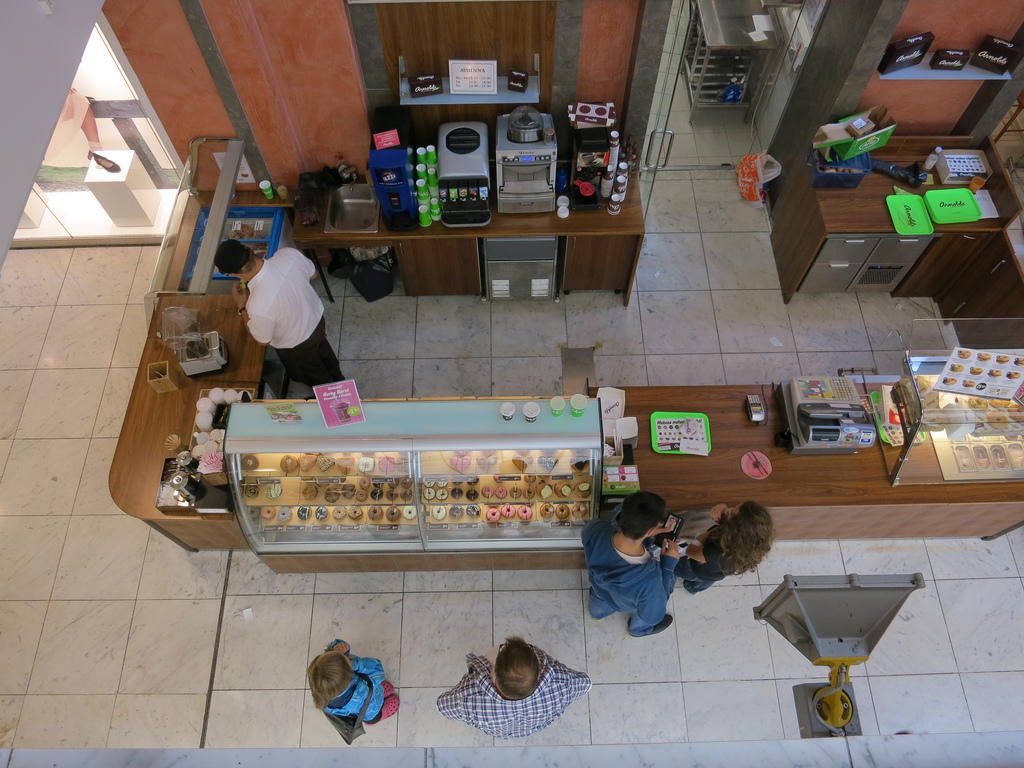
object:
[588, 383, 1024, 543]
counter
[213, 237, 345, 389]
man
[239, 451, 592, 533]
doughnuts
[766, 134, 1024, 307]
desk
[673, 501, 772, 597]
lady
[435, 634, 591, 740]
man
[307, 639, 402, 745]
woman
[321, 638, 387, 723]
shirt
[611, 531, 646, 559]
neck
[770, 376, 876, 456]
cash register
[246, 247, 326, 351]
shirt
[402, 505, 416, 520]
doughnut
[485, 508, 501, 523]
doughnut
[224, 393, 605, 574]
display counter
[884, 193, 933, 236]
tray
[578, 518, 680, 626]
sweater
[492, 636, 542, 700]
head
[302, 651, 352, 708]
head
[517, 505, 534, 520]
donut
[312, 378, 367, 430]
sign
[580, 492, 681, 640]
man